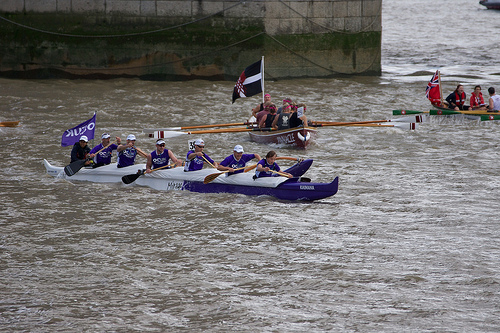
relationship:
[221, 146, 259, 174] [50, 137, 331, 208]
man in kayak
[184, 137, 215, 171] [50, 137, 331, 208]
man in kayak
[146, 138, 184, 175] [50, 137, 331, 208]
man in kayak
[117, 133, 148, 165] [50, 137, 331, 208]
man in kayak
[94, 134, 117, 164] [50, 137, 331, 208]
man in kayak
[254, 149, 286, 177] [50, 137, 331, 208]
woman in kayak